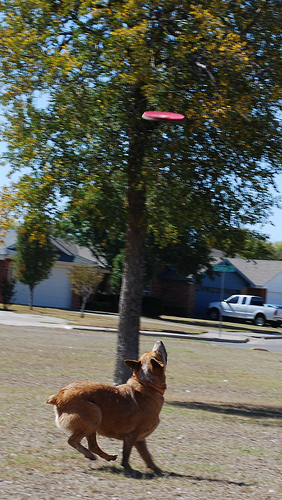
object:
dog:
[46, 339, 168, 477]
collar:
[130, 372, 166, 396]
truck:
[203, 293, 281, 327]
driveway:
[206, 314, 281, 335]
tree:
[2, 2, 281, 388]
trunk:
[112, 192, 148, 389]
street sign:
[210, 263, 237, 274]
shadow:
[88, 465, 258, 487]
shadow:
[162, 395, 281, 427]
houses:
[1, 229, 281, 319]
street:
[0, 318, 282, 352]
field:
[2, 324, 279, 499]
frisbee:
[139, 109, 188, 125]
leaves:
[0, 0, 281, 264]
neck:
[128, 369, 166, 401]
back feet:
[80, 449, 119, 462]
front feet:
[122, 464, 171, 476]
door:
[194, 290, 240, 323]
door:
[10, 266, 73, 309]